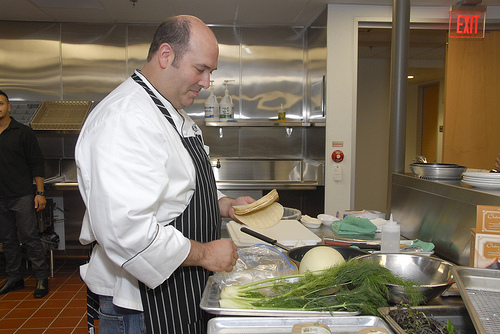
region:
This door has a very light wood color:
[473, 76, 476, 135]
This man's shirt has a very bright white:
[104, 125, 136, 240]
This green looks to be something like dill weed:
[337, 261, 363, 303]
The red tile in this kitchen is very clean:
[31, 305, 36, 329]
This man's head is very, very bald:
[147, 2, 207, 87]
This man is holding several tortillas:
[246, 183, 271, 248]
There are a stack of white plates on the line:
[464, 166, 498, 189]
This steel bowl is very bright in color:
[401, 249, 450, 330]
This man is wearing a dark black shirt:
[3, 127, 6, 205]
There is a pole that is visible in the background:
[388, 30, 410, 172]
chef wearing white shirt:
[77, 17, 247, 331]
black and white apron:
[125, 65, 248, 323]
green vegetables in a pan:
[237, 263, 399, 316]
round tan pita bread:
[227, 189, 289, 232]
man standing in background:
[2, 77, 49, 279]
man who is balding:
[94, 12, 266, 326]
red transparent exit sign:
[441, 5, 496, 40]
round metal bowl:
[337, 249, 476, 301]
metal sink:
[224, 150, 313, 192]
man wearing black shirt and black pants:
[2, 93, 49, 318]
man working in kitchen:
[82, 9, 268, 327]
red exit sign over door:
[421, 10, 498, 90]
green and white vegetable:
[261, 251, 403, 332]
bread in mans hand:
[193, 141, 321, 257]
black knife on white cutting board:
[226, 198, 333, 271]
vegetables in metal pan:
[183, 261, 365, 331]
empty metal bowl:
[365, 232, 452, 304]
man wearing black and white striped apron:
[133, 6, 242, 331]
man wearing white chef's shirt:
[67, 12, 256, 330]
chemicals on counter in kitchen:
[205, 69, 251, 144]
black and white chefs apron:
[115, 59, 252, 332]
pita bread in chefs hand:
[227, 178, 304, 238]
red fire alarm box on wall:
[311, 123, 361, 216]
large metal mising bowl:
[355, 246, 471, 309]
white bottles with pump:
[200, 74, 244, 128]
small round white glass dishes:
[301, 202, 348, 237]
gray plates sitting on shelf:
[408, 146, 470, 186]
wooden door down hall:
[410, 78, 482, 165]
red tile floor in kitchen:
[8, 286, 83, 331]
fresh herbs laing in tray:
[208, 256, 420, 331]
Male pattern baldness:
[119, 8, 258, 80]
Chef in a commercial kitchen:
[11, 16, 498, 298]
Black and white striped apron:
[111, 50, 257, 332]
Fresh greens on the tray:
[234, 253, 424, 330]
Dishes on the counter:
[383, 135, 497, 191]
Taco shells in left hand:
[226, 178, 301, 239]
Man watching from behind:
[1, 73, 92, 308]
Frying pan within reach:
[228, 209, 363, 285]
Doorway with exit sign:
[350, 5, 497, 137]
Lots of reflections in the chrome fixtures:
[11, 19, 333, 201]